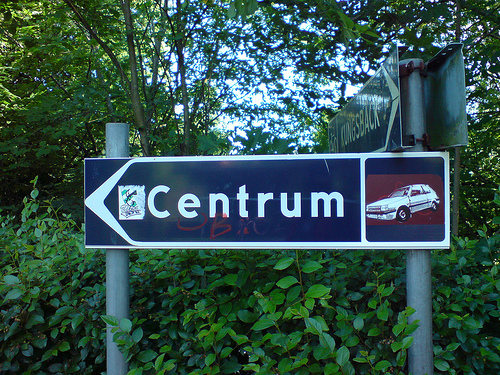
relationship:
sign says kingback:
[321, 40, 472, 153] [336, 91, 383, 148]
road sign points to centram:
[79, 147, 453, 249] [148, 181, 348, 223]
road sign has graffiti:
[79, 147, 453, 249] [175, 201, 325, 239]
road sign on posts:
[79, 147, 453, 249] [98, 64, 439, 372]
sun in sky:
[277, 37, 376, 124] [151, 8, 500, 146]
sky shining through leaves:
[151, 8, 500, 146] [12, 3, 497, 189]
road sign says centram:
[79, 147, 453, 249] [148, 181, 348, 223]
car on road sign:
[365, 179, 440, 222] [79, 147, 453, 249]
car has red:
[365, 179, 440, 222] [362, 174, 442, 223]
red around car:
[362, 174, 442, 223] [365, 179, 440, 222]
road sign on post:
[79, 147, 453, 249] [101, 120, 137, 366]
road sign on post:
[79, 147, 453, 249] [401, 51, 436, 370]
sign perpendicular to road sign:
[321, 40, 472, 153] [79, 147, 453, 249]